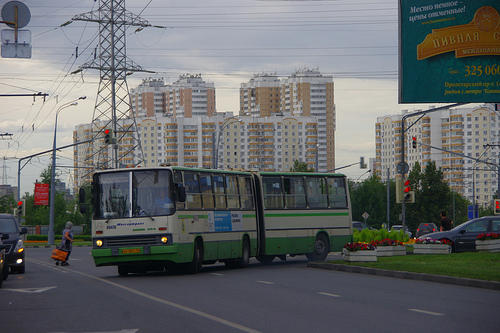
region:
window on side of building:
[465, 142, 475, 153]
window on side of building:
[464, 163, 478, 175]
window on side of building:
[468, 174, 477, 179]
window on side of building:
[466, 131, 474, 137]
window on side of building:
[463, 121, 473, 130]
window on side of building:
[481, 148, 491, 159]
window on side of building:
[470, 129, 477, 134]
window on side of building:
[479, 176, 488, 185]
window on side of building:
[480, 128, 485, 134]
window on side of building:
[481, 127, 491, 137]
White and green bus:
[88, 152, 261, 269]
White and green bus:
[255, 157, 370, 260]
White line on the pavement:
[401, 294, 441, 319]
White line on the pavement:
[310, 281, 343, 307]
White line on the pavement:
[250, 273, 280, 293]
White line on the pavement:
[207, 263, 238, 287]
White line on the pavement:
[173, 303, 254, 331]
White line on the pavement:
[103, 274, 169, 309]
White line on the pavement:
[42, 241, 110, 288]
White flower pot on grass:
[410, 231, 455, 259]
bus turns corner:
[91, 166, 357, 276]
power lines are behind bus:
[55, 2, 161, 242]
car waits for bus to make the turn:
[419, 215, 499, 250]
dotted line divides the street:
[202, 261, 462, 331]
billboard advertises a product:
[396, 0, 499, 108]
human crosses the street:
[49, 219, 76, 265]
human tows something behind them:
[50, 219, 74, 263]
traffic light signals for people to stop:
[395, 171, 416, 206]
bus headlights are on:
[90, 232, 170, 246]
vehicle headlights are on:
[0, 206, 27, 275]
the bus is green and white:
[86, 162, 357, 276]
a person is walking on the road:
[46, 216, 85, 275]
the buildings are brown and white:
[71, 62, 498, 221]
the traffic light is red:
[96, 125, 118, 148]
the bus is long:
[86, 160, 356, 277]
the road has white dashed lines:
[200, 264, 460, 331]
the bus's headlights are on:
[90, 230, 173, 250]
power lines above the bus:
[55, 0, 498, 87]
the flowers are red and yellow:
[341, 231, 418, 254]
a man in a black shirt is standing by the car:
[431, 206, 459, 236]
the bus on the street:
[74, 170, 361, 282]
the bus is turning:
[82, 161, 359, 261]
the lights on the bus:
[89, 230, 173, 247]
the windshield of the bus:
[92, 173, 167, 218]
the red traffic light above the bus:
[102, 127, 119, 144]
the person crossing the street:
[31, 199, 86, 266]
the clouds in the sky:
[229, 7, 375, 80]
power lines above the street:
[35, 15, 117, 113]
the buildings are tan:
[115, 76, 336, 161]